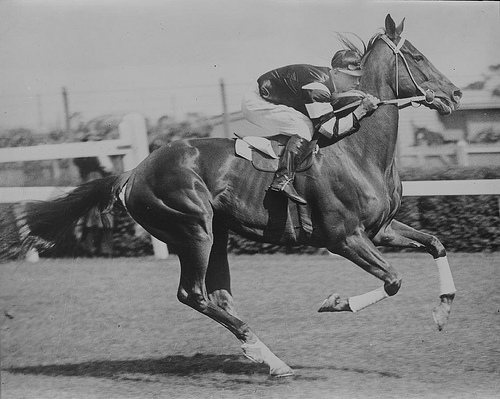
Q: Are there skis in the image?
A: No, there are no skis.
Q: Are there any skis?
A: No, there are no skis.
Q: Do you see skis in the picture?
A: No, there are no skis.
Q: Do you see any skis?
A: No, there are no skis.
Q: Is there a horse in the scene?
A: Yes, there is a horse.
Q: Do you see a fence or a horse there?
A: Yes, there is a horse.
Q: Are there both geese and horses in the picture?
A: No, there is a horse but no geese.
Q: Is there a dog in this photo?
A: No, there are no dogs.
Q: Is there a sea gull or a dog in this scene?
A: No, there are no dogs or seagulls.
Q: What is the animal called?
A: The animal is a horse.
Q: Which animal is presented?
A: The animal is a horse.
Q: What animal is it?
A: The animal is a horse.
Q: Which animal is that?
A: This is a horse.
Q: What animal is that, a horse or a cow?
A: This is a horse.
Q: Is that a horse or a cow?
A: That is a horse.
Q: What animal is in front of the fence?
A: The horse is in front of the fence.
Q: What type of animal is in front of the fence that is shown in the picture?
A: The animal is a horse.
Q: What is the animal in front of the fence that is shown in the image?
A: The animal is a horse.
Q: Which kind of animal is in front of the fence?
A: The animal is a horse.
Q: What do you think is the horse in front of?
A: The horse is in front of the fence.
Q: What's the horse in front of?
A: The horse is in front of the fence.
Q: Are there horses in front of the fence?
A: Yes, there is a horse in front of the fence.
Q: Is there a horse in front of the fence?
A: Yes, there is a horse in front of the fence.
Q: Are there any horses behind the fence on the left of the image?
A: No, the horse is in front of the fence.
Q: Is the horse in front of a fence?
A: Yes, the horse is in front of a fence.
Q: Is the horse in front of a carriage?
A: No, the horse is in front of a fence.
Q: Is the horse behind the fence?
A: No, the horse is in front of the fence.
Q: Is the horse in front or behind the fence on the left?
A: The horse is in front of the fence.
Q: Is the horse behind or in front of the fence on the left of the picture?
A: The horse is in front of the fence.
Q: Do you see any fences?
A: Yes, there is a fence.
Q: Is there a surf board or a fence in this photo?
A: Yes, there is a fence.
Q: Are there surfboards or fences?
A: Yes, there is a fence.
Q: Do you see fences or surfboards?
A: Yes, there is a fence.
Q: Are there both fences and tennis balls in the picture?
A: No, there is a fence but no tennis balls.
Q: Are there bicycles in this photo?
A: No, there are no bicycles.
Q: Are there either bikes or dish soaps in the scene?
A: No, there are no bikes or dish soaps.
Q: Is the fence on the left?
A: Yes, the fence is on the left of the image.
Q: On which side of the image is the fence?
A: The fence is on the left of the image.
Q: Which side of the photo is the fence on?
A: The fence is on the left of the image.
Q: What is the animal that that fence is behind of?
A: The animal is a horse.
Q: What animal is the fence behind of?
A: The fence is behind the horse.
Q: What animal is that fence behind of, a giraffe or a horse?
A: The fence is behind a horse.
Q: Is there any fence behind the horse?
A: Yes, there is a fence behind the horse.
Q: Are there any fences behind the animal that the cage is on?
A: Yes, there is a fence behind the horse.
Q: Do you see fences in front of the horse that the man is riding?
A: No, the fence is behind the horse.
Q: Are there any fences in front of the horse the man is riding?
A: No, the fence is behind the horse.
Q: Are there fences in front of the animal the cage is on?
A: No, the fence is behind the horse.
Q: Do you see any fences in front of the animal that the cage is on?
A: No, the fence is behind the horse.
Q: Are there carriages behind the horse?
A: No, there is a fence behind the horse.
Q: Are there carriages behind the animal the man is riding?
A: No, there is a fence behind the horse.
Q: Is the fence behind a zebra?
A: No, the fence is behind a horse.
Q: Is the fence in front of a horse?
A: No, the fence is behind a horse.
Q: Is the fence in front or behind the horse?
A: The fence is behind the horse.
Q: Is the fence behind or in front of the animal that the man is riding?
A: The fence is behind the horse.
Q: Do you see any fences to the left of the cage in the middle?
A: Yes, there is a fence to the left of the cage.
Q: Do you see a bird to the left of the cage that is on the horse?
A: No, there is a fence to the left of the cage.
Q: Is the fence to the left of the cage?
A: Yes, the fence is to the left of the cage.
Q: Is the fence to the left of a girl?
A: No, the fence is to the left of the cage.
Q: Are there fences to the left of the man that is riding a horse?
A: Yes, there is a fence to the left of the man.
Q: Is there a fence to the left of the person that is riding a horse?
A: Yes, there is a fence to the left of the man.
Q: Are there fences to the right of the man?
A: No, the fence is to the left of the man.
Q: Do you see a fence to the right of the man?
A: No, the fence is to the left of the man.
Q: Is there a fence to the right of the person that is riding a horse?
A: No, the fence is to the left of the man.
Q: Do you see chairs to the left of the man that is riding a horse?
A: No, there is a fence to the left of the man.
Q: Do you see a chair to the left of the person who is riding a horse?
A: No, there is a fence to the left of the man.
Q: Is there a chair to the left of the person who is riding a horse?
A: No, there is a fence to the left of the man.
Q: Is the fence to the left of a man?
A: Yes, the fence is to the left of a man.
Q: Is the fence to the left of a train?
A: No, the fence is to the left of a man.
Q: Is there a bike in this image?
A: No, there are no bikes.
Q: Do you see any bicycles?
A: No, there are no bicycles.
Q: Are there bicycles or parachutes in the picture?
A: No, there are no bicycles or parachutes.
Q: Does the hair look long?
A: Yes, the hair is long.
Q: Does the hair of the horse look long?
A: Yes, the hair is long.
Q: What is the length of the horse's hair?
A: The hair is long.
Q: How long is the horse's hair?
A: The hair is long.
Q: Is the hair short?
A: No, the hair is long.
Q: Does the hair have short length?
A: No, the hair is long.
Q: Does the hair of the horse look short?
A: No, the hair is long.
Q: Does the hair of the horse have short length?
A: No, the hair is long.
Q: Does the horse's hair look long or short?
A: The hair is long.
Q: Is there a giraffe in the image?
A: No, there are no giraffes.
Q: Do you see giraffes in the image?
A: No, there are no giraffes.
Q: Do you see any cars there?
A: No, there are no cars.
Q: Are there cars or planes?
A: No, there are no cars or planes.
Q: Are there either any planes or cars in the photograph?
A: No, there are no cars or planes.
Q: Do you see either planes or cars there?
A: No, there are no cars or planes.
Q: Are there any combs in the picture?
A: No, there are no combs.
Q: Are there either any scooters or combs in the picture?
A: No, there are no combs or scooters.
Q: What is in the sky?
A: The clouds are in the sky.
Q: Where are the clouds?
A: The clouds are in the sky.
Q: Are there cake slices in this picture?
A: No, there are no cake slices.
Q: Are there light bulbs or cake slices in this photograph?
A: No, there are no cake slices or light bulbs.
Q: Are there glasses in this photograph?
A: No, there are no glasses.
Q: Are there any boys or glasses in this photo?
A: No, there are no glasses or boys.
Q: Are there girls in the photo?
A: No, there are no girls.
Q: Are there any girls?
A: No, there are no girls.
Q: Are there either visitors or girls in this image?
A: No, there are no girls or visitors.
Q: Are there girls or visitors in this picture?
A: No, there are no girls or visitors.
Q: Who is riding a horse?
A: The man is riding a horse.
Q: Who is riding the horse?
A: The man is riding a horse.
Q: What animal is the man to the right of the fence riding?
A: The man is riding a horse.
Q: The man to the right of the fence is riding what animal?
A: The man is riding a horse.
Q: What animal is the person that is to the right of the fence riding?
A: The man is riding a horse.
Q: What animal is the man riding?
A: The man is riding a horse.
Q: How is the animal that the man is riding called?
A: The animal is a horse.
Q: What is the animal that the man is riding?
A: The animal is a horse.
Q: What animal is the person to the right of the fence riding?
A: The man is riding a horse.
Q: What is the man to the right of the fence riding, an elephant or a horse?
A: The man is riding a horse.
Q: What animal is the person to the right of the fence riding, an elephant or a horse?
A: The man is riding a horse.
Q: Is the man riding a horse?
A: Yes, the man is riding a horse.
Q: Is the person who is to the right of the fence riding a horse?
A: Yes, the man is riding a horse.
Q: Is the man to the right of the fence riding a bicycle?
A: No, the man is riding a horse.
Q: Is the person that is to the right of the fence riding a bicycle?
A: No, the man is riding a horse.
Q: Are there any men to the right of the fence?
A: Yes, there is a man to the right of the fence.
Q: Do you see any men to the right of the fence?
A: Yes, there is a man to the right of the fence.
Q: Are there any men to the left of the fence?
A: No, the man is to the right of the fence.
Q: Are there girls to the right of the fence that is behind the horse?
A: No, there is a man to the right of the fence.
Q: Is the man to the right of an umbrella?
A: No, the man is to the right of the fence.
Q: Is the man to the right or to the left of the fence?
A: The man is to the right of the fence.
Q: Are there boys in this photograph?
A: No, there are no boys.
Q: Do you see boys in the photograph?
A: No, there are no boys.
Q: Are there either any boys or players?
A: No, there are no boys or players.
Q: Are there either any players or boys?
A: No, there are no boys or players.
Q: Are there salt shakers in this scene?
A: No, there are no salt shakers.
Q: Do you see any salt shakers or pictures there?
A: No, there are no salt shakers or pictures.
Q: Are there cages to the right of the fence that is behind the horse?
A: Yes, there is a cage to the right of the fence.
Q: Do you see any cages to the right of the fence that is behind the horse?
A: Yes, there is a cage to the right of the fence.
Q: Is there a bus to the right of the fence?
A: No, there is a cage to the right of the fence.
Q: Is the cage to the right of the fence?
A: Yes, the cage is to the right of the fence.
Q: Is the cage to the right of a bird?
A: No, the cage is to the right of the fence.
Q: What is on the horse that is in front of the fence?
A: The cage is on the horse.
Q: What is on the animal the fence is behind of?
A: The cage is on the horse.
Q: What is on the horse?
A: The cage is on the horse.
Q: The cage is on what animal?
A: The cage is on the horse.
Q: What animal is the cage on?
A: The cage is on the horse.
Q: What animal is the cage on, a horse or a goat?
A: The cage is on a horse.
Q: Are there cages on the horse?
A: Yes, there is a cage on the horse.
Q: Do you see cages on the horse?
A: Yes, there is a cage on the horse.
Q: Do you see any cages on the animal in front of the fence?
A: Yes, there is a cage on the horse.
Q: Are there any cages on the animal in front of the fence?
A: Yes, there is a cage on the horse.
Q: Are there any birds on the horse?
A: No, there is a cage on the horse.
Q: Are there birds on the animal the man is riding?
A: No, there is a cage on the horse.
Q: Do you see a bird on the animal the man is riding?
A: No, there is a cage on the horse.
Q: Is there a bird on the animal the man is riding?
A: No, there is a cage on the horse.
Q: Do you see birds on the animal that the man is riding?
A: No, there is a cage on the horse.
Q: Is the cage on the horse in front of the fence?
A: Yes, the cage is on the horse.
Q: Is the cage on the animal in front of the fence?
A: Yes, the cage is on the horse.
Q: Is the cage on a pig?
A: No, the cage is on the horse.